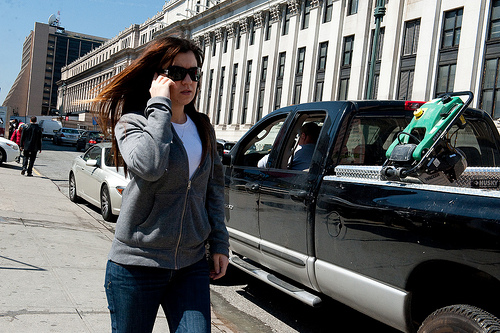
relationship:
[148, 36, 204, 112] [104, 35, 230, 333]
head of woman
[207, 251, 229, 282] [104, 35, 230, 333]
hand of woman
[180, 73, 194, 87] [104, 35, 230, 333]
nose of woman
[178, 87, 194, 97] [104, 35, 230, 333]
mouth of woman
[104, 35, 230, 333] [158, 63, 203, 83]
woman wearing sunglasses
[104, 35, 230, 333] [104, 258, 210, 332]
woman wearing jeans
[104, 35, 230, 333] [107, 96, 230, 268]
woman wearing hoody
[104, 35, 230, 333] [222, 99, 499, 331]
woman near truck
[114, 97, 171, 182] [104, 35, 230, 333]
arm of woman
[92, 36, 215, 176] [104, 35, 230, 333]
hair of woman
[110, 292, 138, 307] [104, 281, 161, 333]
part of thigh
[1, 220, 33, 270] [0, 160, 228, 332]
part of floor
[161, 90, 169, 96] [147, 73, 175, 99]
part of hand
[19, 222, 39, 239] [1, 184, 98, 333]
part of line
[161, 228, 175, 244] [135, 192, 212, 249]
part of pocket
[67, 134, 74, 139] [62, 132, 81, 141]
part of trunk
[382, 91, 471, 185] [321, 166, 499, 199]
equipment in bed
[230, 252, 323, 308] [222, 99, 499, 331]
step to truck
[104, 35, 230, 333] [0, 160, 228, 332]
woman walking on sidewalk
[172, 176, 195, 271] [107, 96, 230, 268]
zipper on jacket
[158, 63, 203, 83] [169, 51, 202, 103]
sunglasses are on face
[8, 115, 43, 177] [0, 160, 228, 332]
people walking on sidewalk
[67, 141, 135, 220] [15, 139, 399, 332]
car parked on road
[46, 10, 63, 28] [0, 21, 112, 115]
dish on top of building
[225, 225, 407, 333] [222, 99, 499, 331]
trim of truck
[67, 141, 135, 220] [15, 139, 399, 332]
car parked on street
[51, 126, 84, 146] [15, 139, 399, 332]
car in street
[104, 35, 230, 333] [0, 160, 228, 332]
woman on sidewalk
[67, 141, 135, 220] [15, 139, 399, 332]
car on road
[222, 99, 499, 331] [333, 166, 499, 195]
truck with tools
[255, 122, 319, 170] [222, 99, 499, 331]
person in truck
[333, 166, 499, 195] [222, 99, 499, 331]
box in truck